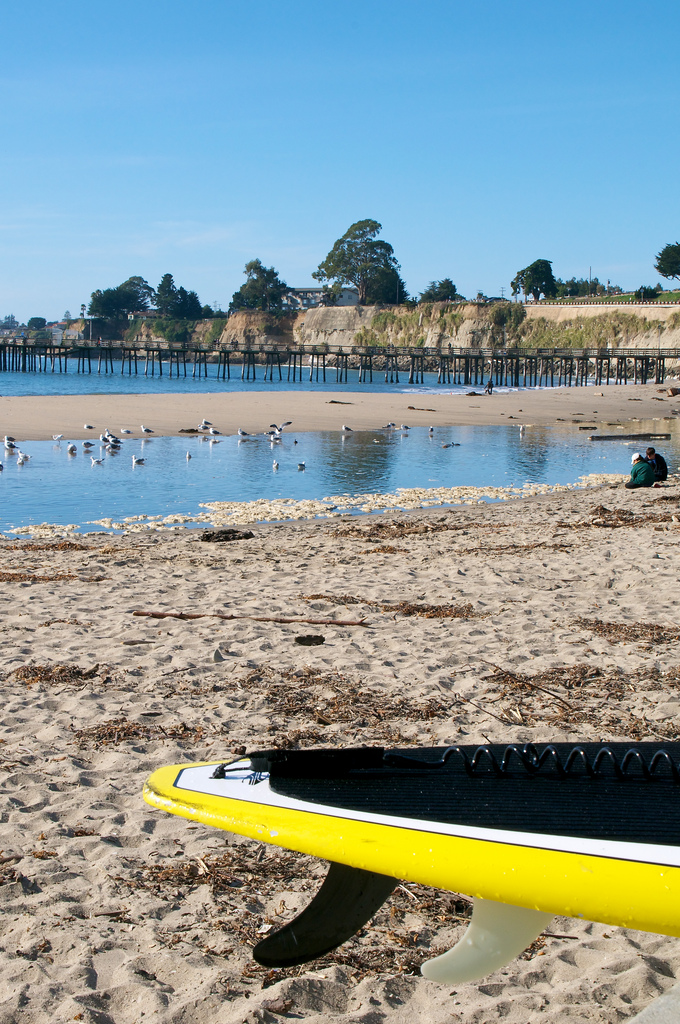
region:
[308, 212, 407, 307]
tall green tree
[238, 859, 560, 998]
black and white fins under surfboard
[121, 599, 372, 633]
long brown stick on sand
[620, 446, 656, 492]
person in green shirt sitting on sand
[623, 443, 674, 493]
two people sitting next to each other on sand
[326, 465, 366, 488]
ripples on surface of water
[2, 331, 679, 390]
long bridge over water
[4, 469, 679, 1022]
sand in front of water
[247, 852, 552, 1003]
two fins on the bottom of the surfboard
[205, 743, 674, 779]
black coiled cord on the surfboard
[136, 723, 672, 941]
yellow black and white surfboard in the sand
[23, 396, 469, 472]
birds on the beach and in the water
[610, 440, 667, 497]
two people sitting on the sand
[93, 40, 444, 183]
clear blue sky above the beach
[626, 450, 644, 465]
person is wearing a white hat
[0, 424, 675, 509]
THIS IS CALM, BLUE WATER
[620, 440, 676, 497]
THIS IS TWO KIDS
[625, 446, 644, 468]
THIS KID IS WEARING A HAT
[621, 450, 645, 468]
THIS KID'S HAT IS WHITE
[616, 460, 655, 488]
THIS KID IS WEARING A GREEN JACKET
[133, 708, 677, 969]
THIS BOAT IS BLACK, YELLOW AND WHITE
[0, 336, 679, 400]
THIS IS A DOCK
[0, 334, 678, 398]
THE DOCK IS VERY LONG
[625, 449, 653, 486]
a person is sitting down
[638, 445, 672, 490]
a person is sitting down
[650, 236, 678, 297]
a tree in a field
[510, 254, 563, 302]
a tree in a field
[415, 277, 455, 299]
a tree in a field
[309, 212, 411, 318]
a tree in a field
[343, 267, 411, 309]
a tree in a field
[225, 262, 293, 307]
a tree in a field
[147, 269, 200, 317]
a tree in a field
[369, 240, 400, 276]
green leaves on the tree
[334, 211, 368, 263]
green leaves on the tree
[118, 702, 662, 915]
yellow black and white board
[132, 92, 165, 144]
white clouds in blue sky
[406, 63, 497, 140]
white clouds in blue sky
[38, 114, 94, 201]
white clouds in blue sky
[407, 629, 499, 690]
Large body of sand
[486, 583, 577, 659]
Large body of sand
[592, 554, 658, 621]
Large body of sand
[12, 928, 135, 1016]
Large body of sand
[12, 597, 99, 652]
Large body of sand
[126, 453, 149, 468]
Bird in the pond of water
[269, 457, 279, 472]
Bird in the pond of water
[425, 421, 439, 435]
Bird in the pond of water